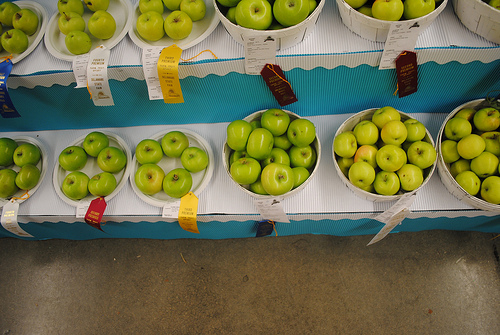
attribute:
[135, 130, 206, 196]
apples — GREEN 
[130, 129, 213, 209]
plate — WHITE 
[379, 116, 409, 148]
apple — green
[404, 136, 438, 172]
apple — green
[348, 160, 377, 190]
apple — green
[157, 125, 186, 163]
apple — green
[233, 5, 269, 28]
apple — green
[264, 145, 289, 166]
apple — green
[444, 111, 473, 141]
apple — green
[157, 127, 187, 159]
apple — green